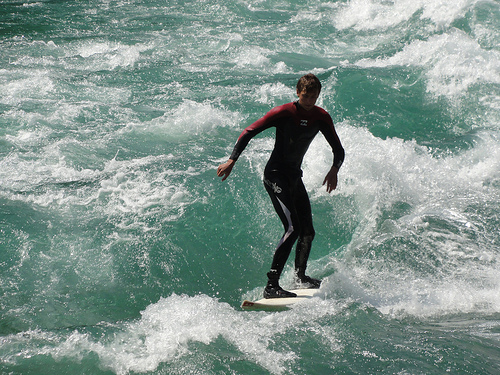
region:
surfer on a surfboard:
[198, 48, 399, 327]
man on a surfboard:
[212, 68, 360, 320]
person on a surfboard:
[210, 63, 355, 325]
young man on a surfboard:
[205, 67, 361, 330]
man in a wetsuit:
[220, 62, 347, 327]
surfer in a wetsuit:
[205, 70, 347, 320]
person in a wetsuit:
[215, 70, 367, 344]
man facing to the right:
[210, 50, 355, 328]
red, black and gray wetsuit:
[237, 107, 344, 292]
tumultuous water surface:
[41, 104, 444, 366]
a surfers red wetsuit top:
[230, 100, 356, 168]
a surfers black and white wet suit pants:
[264, 164, 316, 278]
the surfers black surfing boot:
[262, 272, 298, 299]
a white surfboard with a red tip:
[241, 288, 316, 311]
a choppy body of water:
[357, 9, 498, 334]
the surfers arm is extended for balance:
[216, 103, 293, 181]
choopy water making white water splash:
[0, 0, 220, 372]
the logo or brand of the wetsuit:
[297, 115, 311, 129]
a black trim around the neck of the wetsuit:
[291, 98, 319, 115]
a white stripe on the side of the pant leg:
[274, 194, 296, 256]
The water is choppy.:
[1, 4, 498, 367]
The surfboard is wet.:
[241, 282, 344, 314]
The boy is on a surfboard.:
[210, 62, 348, 308]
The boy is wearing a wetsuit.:
[208, 63, 353, 310]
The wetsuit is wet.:
[206, 68, 359, 316]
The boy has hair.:
[215, 65, 349, 312]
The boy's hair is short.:
[288, 64, 327, 116]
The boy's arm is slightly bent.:
[293, 64, 353, 201]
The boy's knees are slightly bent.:
[207, 60, 352, 312]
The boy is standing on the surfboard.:
[212, 63, 353, 314]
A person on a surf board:
[215, 72, 343, 309]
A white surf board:
[236, 280, 317, 310]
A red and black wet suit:
[227, 101, 342, 291]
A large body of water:
[0, 0, 495, 365]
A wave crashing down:
[232, 126, 437, 241]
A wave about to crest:
[96, 162, 256, 302]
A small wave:
[140, 65, 365, 140]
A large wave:
[0, 130, 499, 345]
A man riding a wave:
[217, 70, 342, 314]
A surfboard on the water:
[243, 280, 333, 310]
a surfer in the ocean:
[205, 65, 357, 317]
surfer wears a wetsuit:
[211, 60, 356, 322]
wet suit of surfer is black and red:
[217, 49, 352, 304]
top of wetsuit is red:
[228, 103, 347, 165]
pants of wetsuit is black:
[250, 157, 336, 308]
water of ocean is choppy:
[9, 0, 497, 367]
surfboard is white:
[231, 272, 346, 318]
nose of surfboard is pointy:
[230, 290, 270, 317]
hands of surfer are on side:
[204, 66, 364, 218]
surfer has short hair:
[266, 60, 341, 135]